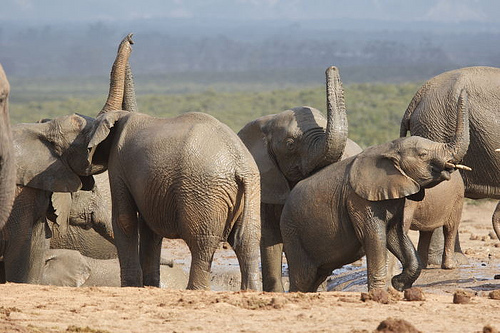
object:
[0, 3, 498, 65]
sky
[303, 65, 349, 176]
trunk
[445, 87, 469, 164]
trunk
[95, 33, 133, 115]
trunk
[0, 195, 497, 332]
ground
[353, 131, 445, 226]
ground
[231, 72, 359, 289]
elephant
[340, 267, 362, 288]
water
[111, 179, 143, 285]
leg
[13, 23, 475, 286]
elephant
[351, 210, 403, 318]
leg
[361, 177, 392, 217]
ground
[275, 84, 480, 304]
bare trees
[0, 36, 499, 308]
elephants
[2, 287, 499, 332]
ground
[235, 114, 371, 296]
elephant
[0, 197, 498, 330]
dirt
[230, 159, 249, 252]
tail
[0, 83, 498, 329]
field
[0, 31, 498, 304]
herd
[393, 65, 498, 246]
elephant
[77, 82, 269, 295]
elephant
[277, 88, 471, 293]
elephant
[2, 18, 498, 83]
trees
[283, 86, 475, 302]
small elephant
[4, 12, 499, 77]
hill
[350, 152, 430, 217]
ear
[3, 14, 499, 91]
hills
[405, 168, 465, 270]
elephant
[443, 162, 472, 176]
tusks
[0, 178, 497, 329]
mud hole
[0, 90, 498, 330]
land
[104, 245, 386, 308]
hole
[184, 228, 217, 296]
leg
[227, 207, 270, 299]
leg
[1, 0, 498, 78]
fog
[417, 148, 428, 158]
eye